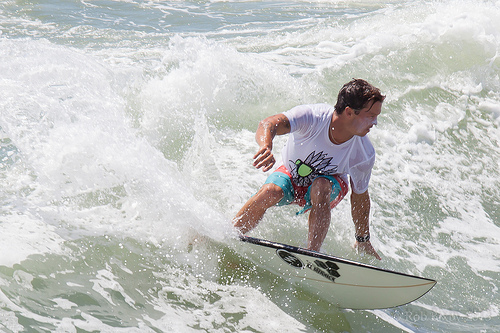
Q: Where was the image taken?
A: It was taken at the ocean.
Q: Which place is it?
A: It is an ocean.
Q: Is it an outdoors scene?
A: Yes, it is outdoors.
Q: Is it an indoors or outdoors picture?
A: It is outdoors.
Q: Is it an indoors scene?
A: No, it is outdoors.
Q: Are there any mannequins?
A: No, there are no mannequins.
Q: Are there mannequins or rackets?
A: No, there are no mannequins or rackets.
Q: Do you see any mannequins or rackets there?
A: No, there are no mannequins or rackets.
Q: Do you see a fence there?
A: No, there are no fences.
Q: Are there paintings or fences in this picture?
A: No, there are no fences or paintings.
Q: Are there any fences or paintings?
A: No, there are no fences or paintings.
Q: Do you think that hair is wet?
A: Yes, the hair is wet.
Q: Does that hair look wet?
A: Yes, the hair is wet.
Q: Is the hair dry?
A: No, the hair is wet.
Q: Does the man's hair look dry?
A: No, the hair is wet.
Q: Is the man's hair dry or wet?
A: The hair is wet.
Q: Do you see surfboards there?
A: Yes, there is a surfboard.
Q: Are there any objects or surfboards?
A: Yes, there is a surfboard.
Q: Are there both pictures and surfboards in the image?
A: No, there is a surfboard but no pictures.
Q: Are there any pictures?
A: No, there are no pictures.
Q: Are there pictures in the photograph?
A: No, there are no pictures.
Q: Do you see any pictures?
A: No, there are no pictures.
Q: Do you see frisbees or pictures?
A: No, there are no pictures or frisbees.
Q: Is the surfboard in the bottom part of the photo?
A: Yes, the surfboard is in the bottom of the image.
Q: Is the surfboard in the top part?
A: No, the surfboard is in the bottom of the image.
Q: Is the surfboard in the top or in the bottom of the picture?
A: The surfboard is in the bottom of the image.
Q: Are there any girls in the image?
A: No, there are no girls.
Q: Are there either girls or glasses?
A: No, there are no girls or glasses.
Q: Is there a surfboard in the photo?
A: Yes, there is a surfboard.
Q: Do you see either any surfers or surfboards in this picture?
A: Yes, there is a surfboard.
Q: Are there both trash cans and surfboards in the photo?
A: No, there is a surfboard but no trash cans.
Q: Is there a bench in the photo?
A: No, there are no benches.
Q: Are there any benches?
A: No, there are no benches.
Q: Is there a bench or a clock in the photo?
A: No, there are no benches or clocks.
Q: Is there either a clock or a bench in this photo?
A: No, there are no benches or clocks.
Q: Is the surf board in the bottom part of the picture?
A: Yes, the surf board is in the bottom of the image.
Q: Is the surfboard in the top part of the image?
A: No, the surfboard is in the bottom of the image.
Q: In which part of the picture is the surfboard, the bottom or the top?
A: The surfboard is in the bottom of the image.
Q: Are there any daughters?
A: No, there are no daughters.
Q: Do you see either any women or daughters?
A: No, there are no daughters or women.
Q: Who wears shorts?
A: The man wears shorts.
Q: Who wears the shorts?
A: The man wears shorts.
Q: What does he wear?
A: The man wears shorts.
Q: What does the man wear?
A: The man wears shorts.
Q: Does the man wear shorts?
A: Yes, the man wears shorts.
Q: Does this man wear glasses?
A: No, the man wears shorts.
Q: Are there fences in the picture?
A: No, there are no fences.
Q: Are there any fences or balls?
A: No, there are no fences or balls.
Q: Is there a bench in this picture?
A: No, there are no benches.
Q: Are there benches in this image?
A: No, there are no benches.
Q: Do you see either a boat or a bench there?
A: No, there are no benches or boats.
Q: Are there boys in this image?
A: No, there are no boys.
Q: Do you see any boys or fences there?
A: No, there are no boys or fences.